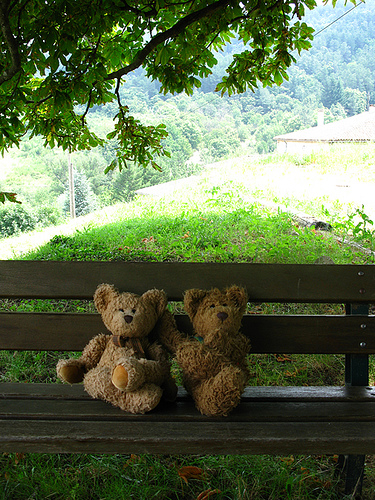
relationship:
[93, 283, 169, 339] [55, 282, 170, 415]
head of teddy bear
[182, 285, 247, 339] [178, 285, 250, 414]
head of teddy bear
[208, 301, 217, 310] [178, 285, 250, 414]
eye of teddy bear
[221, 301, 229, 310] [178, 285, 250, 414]
eye of teddy bear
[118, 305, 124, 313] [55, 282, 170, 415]
eye of teddy bear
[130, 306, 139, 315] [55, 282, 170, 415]
eye of teddy bear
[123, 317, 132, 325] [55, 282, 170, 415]
nose of teddy bear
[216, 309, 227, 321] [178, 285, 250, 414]
nose of teddy bear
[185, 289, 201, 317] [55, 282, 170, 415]
ear of teddy bear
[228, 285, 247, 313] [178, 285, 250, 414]
ear of teddy bear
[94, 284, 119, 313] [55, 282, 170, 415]
ear of teddy bear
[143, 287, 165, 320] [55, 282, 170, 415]
ear of teddy bear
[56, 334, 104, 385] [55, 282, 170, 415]
arm of teddy bear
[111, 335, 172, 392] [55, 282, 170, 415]
arm of teddy bear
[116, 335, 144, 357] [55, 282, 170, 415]
ribbon on teddy bear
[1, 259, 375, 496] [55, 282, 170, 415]
bench behind teddy bear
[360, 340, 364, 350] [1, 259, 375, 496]
bolt in bench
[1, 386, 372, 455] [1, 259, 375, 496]
seat of bench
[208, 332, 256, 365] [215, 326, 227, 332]
arm on mouth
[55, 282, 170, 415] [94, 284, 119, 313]
teddy bear has an ear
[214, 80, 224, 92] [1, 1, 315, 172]
leave of tree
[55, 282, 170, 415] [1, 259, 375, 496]
teddy bear sitting on bench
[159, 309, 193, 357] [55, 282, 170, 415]
arm on teddy bear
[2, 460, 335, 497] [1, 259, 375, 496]
grass under bench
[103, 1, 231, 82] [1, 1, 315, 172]
limb of tree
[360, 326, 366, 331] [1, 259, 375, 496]
bolt on bench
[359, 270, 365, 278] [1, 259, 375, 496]
bolt on bench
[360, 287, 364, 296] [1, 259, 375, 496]
bolt on bench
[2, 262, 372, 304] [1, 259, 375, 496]
plank on bench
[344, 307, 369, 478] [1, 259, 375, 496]
support for bench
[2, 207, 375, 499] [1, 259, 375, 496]
grass behind bench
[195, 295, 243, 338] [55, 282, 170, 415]
face of teddy bear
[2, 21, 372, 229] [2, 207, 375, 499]
forrest behind grass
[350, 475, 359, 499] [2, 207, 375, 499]
twig in grass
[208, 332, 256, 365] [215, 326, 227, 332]
arm covering mouth